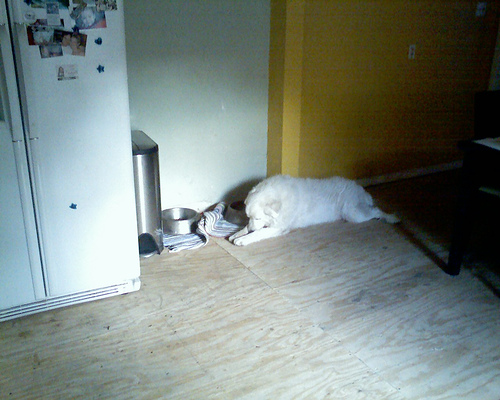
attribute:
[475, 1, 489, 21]
light switch — white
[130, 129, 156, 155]
lid — black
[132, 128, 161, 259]
trash can — metal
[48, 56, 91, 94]
magnet — rectangular, refrigerator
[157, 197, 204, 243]
pet dish — metal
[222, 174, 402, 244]
dog — white 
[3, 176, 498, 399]
floor — PLYWOOD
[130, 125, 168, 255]
can — SILVER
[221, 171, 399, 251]
dog — WHITE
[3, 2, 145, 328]
fridge — white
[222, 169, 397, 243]
dog — SLEEPING